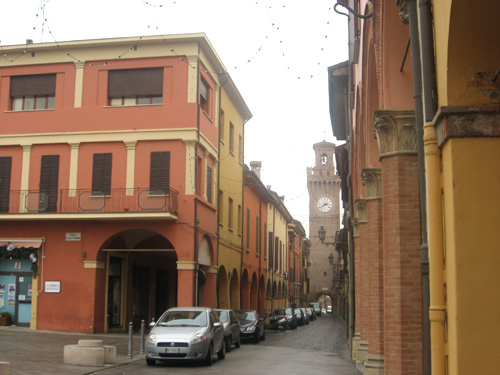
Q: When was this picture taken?
A: Daytime.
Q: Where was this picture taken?
A: In the town.